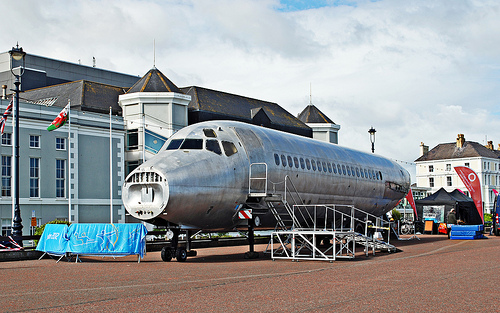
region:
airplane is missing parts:
[122, 117, 409, 262]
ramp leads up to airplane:
[247, 163, 402, 261]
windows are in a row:
[271, 148, 383, 185]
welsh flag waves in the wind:
[43, 96, 73, 220]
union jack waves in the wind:
[0, 80, 26, 242]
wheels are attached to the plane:
[154, 223, 193, 262]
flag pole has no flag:
[106, 103, 116, 225]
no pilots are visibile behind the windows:
[163, 133, 239, 159]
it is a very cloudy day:
[1, 2, 498, 159]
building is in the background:
[416, 134, 499, 228]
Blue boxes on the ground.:
[443, 220, 483, 245]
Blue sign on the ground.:
[35, 216, 151, 265]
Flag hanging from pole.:
[47, 97, 79, 129]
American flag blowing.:
[3, 86, 22, 134]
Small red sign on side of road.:
[28, 208, 43, 247]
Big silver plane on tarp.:
[126, 108, 412, 240]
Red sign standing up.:
[450, 160, 490, 225]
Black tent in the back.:
[418, 188, 463, 235]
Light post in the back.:
[366, 125, 383, 151]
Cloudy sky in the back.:
[365, 68, 452, 125]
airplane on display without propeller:
[115, 166, 172, 220]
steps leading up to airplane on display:
[248, 188, 406, 264]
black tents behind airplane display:
[415, 186, 483, 238]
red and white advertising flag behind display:
[446, 163, 493, 227]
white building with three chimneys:
[403, 130, 498, 240]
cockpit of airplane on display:
[165, 135, 244, 162]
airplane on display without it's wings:
[121, 120, 410, 230]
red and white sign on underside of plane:
[231, 204, 258, 223]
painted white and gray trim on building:
[61, 130, 83, 230]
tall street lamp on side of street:
[6, 43, 30, 248]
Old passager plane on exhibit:
[109, 122, 406, 219]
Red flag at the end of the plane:
[451, 160, 489, 217]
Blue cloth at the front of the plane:
[39, 221, 148, 262]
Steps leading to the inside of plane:
[249, 167, 400, 271]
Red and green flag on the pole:
[45, 98, 70, 133]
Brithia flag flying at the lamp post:
[0, 103, 13, 126]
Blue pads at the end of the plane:
[450, 225, 480, 240]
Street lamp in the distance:
[363, 123, 380, 154]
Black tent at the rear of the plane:
[416, 183, 485, 237]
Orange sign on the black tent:
[420, 219, 436, 232]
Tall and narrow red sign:
[451, 164, 484, 226]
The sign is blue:
[41, 219, 144, 264]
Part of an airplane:
[124, 119, 410, 251]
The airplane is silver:
[124, 119, 411, 250]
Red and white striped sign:
[236, 210, 255, 222]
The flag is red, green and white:
[46, 102, 68, 132]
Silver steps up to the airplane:
[255, 183, 393, 261]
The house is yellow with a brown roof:
[415, 139, 498, 211]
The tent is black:
[418, 187, 477, 237]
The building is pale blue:
[6, 94, 126, 241]